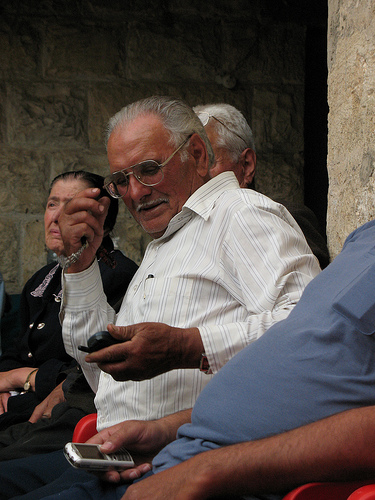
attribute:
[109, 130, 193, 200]
eyeglasses — metal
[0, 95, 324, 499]
man — old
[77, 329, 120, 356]
phone — black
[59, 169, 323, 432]
shirt — white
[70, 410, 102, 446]
seat — red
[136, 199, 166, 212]
mustache — grey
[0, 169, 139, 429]
woman — sitting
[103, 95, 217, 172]
hair — grey, silver, gray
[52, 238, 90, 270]
watch — metal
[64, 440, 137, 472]
phone — silver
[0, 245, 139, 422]
shirt — black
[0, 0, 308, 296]
wall — stone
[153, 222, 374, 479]
shirt — blue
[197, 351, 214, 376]
watch — silver